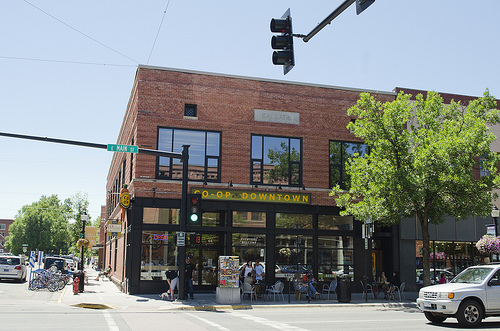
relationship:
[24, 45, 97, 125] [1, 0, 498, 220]
white clouds in blue sky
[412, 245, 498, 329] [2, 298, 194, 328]
vehicle approaching intersection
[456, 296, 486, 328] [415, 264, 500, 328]
wheel of vehicle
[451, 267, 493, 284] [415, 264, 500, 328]
windshield on vehicle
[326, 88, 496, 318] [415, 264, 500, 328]
tree by vehicle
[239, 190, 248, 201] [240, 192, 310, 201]
d in downtown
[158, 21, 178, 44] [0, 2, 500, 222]
clouds in sky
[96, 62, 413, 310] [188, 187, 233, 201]
building saying co-op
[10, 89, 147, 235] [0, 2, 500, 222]
clouds in sky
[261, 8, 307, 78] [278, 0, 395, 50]
light on pole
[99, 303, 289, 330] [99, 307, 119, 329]
crosswalk has line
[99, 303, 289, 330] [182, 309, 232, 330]
crosswalk has line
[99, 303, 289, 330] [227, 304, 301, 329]
crosswalk has line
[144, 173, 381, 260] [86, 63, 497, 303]
sign on building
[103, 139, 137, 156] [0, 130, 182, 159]
street sign on pole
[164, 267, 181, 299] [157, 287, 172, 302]
man walking dog